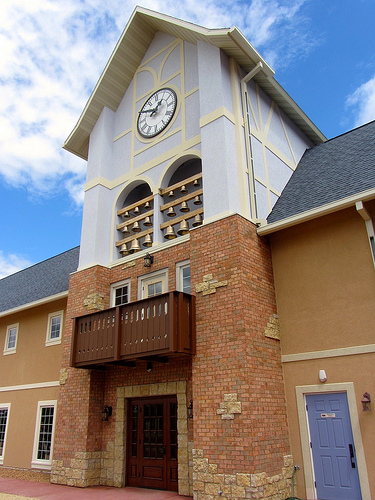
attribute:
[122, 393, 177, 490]
door — red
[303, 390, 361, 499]
door — blue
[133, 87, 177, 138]
clock — black, white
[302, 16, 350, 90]
blue sky — above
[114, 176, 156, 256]
nine bells — row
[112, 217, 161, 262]
six bells — row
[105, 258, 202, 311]
three windows — behind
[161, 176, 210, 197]
three bells — row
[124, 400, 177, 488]
burgundy door — burgandy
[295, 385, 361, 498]
"purple door — purple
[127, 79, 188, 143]
clock on building — round, black, white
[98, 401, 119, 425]
"black lamp — black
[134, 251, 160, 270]
lamp above balcony — black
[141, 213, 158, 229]
"gold bell — gold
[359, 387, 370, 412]
"small lamp — small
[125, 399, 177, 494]
"brown door — brown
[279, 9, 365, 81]
sunny blue sky — clear